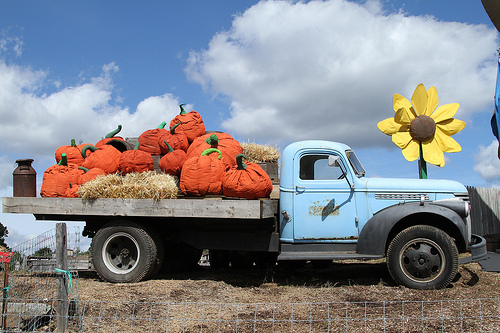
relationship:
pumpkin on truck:
[176, 139, 240, 192] [37, 95, 464, 312]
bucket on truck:
[12, 158, 38, 196] [261, 129, 444, 296]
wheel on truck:
[83, 228, 176, 285] [11, 139, 477, 291]